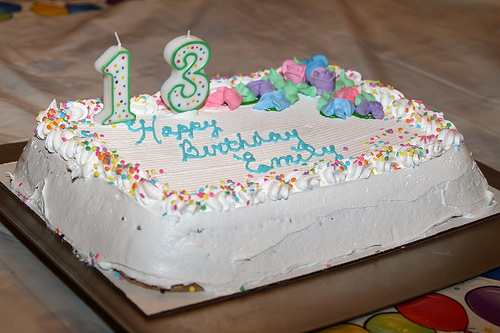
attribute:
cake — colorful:
[6, 53, 498, 281]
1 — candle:
[95, 30, 137, 125]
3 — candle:
[163, 30, 210, 111]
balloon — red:
[395, 294, 467, 332]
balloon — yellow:
[364, 313, 435, 333]